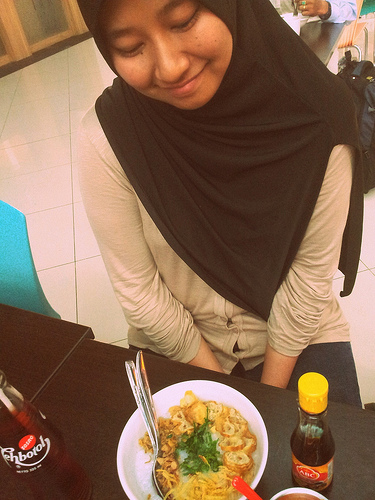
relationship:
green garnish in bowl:
[172, 414, 221, 480] [115, 379, 269, 499]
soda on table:
[0, 372, 95, 498] [8, 329, 371, 497]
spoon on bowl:
[135, 347, 165, 497] [115, 379, 269, 499]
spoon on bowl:
[124, 359, 155, 459] [115, 379, 269, 499]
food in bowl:
[137, 390, 257, 498] [115, 379, 269, 499]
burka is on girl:
[72, 0, 362, 320] [72, 1, 365, 411]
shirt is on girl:
[69, 85, 356, 379] [72, 1, 365, 411]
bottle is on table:
[264, 356, 345, 499] [3, 372, 367, 497]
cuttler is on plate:
[130, 346, 166, 498] [112, 376, 272, 498]